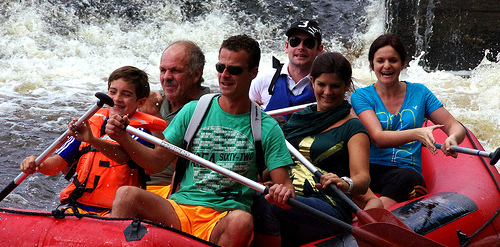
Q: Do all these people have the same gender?
A: No, they are both male and female.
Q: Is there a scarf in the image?
A: Yes, there is a scarf.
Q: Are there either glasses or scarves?
A: Yes, there is a scarf.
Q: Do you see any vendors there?
A: No, there are no vendors.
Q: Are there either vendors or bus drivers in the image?
A: No, there are no vendors or bus drivers.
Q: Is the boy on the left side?
A: Yes, the boy is on the left of the image.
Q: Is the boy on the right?
A: No, the boy is on the left of the image.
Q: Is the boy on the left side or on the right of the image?
A: The boy is on the left of the image.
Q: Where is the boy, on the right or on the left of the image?
A: The boy is on the left of the image.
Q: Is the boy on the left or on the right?
A: The boy is on the left of the image.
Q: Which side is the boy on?
A: The boy is on the left of the image.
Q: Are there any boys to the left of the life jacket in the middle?
A: Yes, there is a boy to the left of the life jacket.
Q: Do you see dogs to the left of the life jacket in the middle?
A: No, there is a boy to the left of the life vest.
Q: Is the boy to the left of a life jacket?
A: Yes, the boy is to the left of a life jacket.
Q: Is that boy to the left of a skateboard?
A: No, the boy is to the left of a life jacket.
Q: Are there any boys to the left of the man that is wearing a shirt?
A: Yes, there is a boy to the left of the man.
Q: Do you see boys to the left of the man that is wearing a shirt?
A: Yes, there is a boy to the left of the man.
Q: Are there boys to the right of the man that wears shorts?
A: No, the boy is to the left of the man.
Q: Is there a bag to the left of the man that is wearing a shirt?
A: No, there is a boy to the left of the man.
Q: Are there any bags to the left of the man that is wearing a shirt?
A: No, there is a boy to the left of the man.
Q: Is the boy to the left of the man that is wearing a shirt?
A: Yes, the boy is to the left of the man.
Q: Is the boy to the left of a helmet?
A: No, the boy is to the left of the man.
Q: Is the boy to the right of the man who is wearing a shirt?
A: No, the boy is to the left of the man.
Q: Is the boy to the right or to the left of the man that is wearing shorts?
A: The boy is to the left of the man.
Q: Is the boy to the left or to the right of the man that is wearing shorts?
A: The boy is to the left of the man.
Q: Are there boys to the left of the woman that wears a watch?
A: Yes, there is a boy to the left of the woman.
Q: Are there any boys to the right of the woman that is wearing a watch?
A: No, the boy is to the left of the woman.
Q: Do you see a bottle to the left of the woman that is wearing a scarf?
A: No, there is a boy to the left of the woman.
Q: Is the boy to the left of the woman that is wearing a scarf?
A: Yes, the boy is to the left of the woman.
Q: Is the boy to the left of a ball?
A: No, the boy is to the left of the woman.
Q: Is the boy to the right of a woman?
A: No, the boy is to the left of a woman.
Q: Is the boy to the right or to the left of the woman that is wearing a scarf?
A: The boy is to the left of the woman.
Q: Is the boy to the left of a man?
A: Yes, the boy is to the left of a man.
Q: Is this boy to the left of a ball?
A: No, the boy is to the left of a man.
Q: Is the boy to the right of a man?
A: No, the boy is to the left of a man.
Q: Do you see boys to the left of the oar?
A: Yes, there is a boy to the left of the oar.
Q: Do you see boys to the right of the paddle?
A: No, the boy is to the left of the paddle.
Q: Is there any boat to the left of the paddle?
A: No, there is a boy to the left of the paddle.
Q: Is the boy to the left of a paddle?
A: Yes, the boy is to the left of a paddle.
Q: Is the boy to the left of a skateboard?
A: No, the boy is to the left of a paddle.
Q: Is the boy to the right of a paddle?
A: No, the boy is to the left of a paddle.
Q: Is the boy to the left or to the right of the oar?
A: The boy is to the left of the oar.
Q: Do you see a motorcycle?
A: No, there are no motorcycles.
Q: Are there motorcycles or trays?
A: No, there are no motorcycles or trays.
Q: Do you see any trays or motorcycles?
A: No, there are no motorcycles or trays.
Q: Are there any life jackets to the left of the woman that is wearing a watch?
A: Yes, there is a life jacket to the left of the woman.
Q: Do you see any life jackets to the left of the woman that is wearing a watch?
A: Yes, there is a life jacket to the left of the woman.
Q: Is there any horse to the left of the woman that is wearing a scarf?
A: No, there is a life jacket to the left of the woman.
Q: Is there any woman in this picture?
A: Yes, there is a woman.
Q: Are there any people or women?
A: Yes, there is a woman.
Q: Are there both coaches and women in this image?
A: No, there is a woman but no coaches.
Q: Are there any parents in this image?
A: No, there are no parents.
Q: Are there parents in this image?
A: No, there are no parents.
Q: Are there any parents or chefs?
A: No, there are no parents or chefs.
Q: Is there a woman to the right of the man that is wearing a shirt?
A: Yes, there is a woman to the right of the man.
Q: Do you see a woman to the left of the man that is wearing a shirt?
A: No, the woman is to the right of the man.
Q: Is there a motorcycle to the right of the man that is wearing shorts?
A: No, there is a woman to the right of the man.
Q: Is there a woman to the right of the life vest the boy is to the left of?
A: Yes, there is a woman to the right of the life vest.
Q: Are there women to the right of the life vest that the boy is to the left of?
A: Yes, there is a woman to the right of the life vest.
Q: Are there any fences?
A: No, there are no fences.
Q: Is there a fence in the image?
A: No, there are no fences.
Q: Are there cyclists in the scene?
A: No, there are no cyclists.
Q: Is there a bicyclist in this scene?
A: No, there are no cyclists.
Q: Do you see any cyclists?
A: No, there are no cyclists.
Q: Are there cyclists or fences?
A: No, there are no cyclists or fences.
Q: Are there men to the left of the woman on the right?
A: Yes, there is a man to the left of the woman.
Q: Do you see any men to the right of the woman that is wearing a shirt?
A: No, the man is to the left of the woman.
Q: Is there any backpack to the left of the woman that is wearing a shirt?
A: No, there is a man to the left of the woman.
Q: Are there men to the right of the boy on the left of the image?
A: Yes, there is a man to the right of the boy.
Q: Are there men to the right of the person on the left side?
A: Yes, there is a man to the right of the boy.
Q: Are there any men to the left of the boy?
A: No, the man is to the right of the boy.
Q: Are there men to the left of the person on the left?
A: No, the man is to the right of the boy.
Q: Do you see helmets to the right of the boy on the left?
A: No, there is a man to the right of the boy.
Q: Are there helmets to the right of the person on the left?
A: No, there is a man to the right of the boy.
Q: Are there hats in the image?
A: Yes, there is a hat.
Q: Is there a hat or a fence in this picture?
A: Yes, there is a hat.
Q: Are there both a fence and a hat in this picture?
A: No, there is a hat but no fences.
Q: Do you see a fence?
A: No, there are no fences.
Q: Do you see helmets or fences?
A: No, there are no fences or helmets.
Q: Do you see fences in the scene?
A: No, there are no fences.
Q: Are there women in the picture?
A: Yes, there is a woman.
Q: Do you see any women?
A: Yes, there is a woman.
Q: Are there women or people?
A: Yes, there is a woman.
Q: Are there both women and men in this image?
A: Yes, there are both a woman and a man.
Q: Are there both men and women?
A: Yes, there are both a woman and a man.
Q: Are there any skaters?
A: No, there are no skaters.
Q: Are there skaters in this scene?
A: No, there are no skaters.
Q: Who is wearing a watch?
A: The woman is wearing a watch.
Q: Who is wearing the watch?
A: The woman is wearing a watch.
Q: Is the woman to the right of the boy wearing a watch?
A: Yes, the woman is wearing a watch.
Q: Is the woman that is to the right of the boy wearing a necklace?
A: No, the woman is wearing a watch.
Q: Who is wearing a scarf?
A: The woman is wearing a scarf.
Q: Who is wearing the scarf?
A: The woman is wearing a scarf.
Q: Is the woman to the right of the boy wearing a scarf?
A: Yes, the woman is wearing a scarf.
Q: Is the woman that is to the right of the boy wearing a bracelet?
A: No, the woman is wearing a scarf.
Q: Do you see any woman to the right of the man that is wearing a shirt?
A: Yes, there is a woman to the right of the man.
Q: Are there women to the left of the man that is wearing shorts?
A: No, the woman is to the right of the man.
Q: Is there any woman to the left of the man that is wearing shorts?
A: No, the woman is to the right of the man.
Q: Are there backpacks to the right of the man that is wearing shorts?
A: No, there is a woman to the right of the man.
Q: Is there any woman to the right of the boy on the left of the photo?
A: Yes, there is a woman to the right of the boy.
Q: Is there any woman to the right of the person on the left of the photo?
A: Yes, there is a woman to the right of the boy.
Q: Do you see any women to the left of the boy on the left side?
A: No, the woman is to the right of the boy.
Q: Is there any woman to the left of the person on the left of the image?
A: No, the woman is to the right of the boy.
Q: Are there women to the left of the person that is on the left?
A: No, the woman is to the right of the boy.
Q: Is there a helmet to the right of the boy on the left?
A: No, there is a woman to the right of the boy.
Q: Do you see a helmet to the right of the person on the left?
A: No, there is a woman to the right of the boy.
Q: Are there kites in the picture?
A: No, there are no kites.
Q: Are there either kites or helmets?
A: No, there are no kites or helmets.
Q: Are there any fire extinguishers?
A: No, there are no fire extinguishers.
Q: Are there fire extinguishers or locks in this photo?
A: No, there are no fire extinguishers or locks.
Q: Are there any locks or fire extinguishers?
A: No, there are no fire extinguishers or locks.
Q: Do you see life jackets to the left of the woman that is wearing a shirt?
A: Yes, there is a life jacket to the left of the woman.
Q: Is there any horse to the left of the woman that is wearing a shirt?
A: No, there is a life jacket to the left of the woman.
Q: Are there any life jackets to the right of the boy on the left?
A: Yes, there is a life jacket to the right of the boy.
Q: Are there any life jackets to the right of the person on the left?
A: Yes, there is a life jacket to the right of the boy.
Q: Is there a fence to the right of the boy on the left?
A: No, there is a life jacket to the right of the boy.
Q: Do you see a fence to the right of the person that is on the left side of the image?
A: No, there is a life jacket to the right of the boy.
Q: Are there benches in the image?
A: No, there are no benches.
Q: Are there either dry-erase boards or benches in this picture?
A: No, there are no benches or dry-erase boards.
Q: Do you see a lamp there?
A: No, there are no lamps.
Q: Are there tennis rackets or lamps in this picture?
A: No, there are no lamps or tennis rackets.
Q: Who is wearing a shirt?
A: The man is wearing a shirt.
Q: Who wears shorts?
A: The man wears shorts.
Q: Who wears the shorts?
A: The man wears shorts.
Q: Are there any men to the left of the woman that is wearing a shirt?
A: Yes, there is a man to the left of the woman.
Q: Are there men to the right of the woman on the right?
A: No, the man is to the left of the woman.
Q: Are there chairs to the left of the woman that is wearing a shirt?
A: No, there is a man to the left of the woman.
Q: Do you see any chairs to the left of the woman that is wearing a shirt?
A: No, there is a man to the left of the woman.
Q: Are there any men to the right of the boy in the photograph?
A: Yes, there is a man to the right of the boy.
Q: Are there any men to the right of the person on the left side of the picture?
A: Yes, there is a man to the right of the boy.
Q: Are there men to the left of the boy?
A: No, the man is to the right of the boy.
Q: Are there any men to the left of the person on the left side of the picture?
A: No, the man is to the right of the boy.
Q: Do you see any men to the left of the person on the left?
A: No, the man is to the right of the boy.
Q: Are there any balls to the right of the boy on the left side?
A: No, there is a man to the right of the boy.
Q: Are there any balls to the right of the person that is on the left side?
A: No, there is a man to the right of the boy.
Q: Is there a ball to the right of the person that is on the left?
A: No, there is a man to the right of the boy.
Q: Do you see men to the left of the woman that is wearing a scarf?
A: Yes, there is a man to the left of the woman.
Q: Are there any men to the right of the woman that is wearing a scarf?
A: No, the man is to the left of the woman.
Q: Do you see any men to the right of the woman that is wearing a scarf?
A: No, the man is to the left of the woman.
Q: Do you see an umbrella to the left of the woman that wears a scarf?
A: No, there is a man to the left of the woman.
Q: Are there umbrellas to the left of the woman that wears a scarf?
A: No, there is a man to the left of the woman.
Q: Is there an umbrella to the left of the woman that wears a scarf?
A: No, there is a man to the left of the woman.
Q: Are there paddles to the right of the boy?
A: Yes, there is a paddle to the right of the boy.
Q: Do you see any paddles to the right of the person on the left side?
A: Yes, there is a paddle to the right of the boy.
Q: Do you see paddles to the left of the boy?
A: No, the paddle is to the right of the boy.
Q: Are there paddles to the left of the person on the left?
A: No, the paddle is to the right of the boy.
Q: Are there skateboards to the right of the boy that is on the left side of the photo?
A: No, there is a paddle to the right of the boy.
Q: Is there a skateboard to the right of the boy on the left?
A: No, there is a paddle to the right of the boy.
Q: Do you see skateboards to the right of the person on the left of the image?
A: No, there is a paddle to the right of the boy.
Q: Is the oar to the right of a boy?
A: Yes, the oar is to the right of a boy.